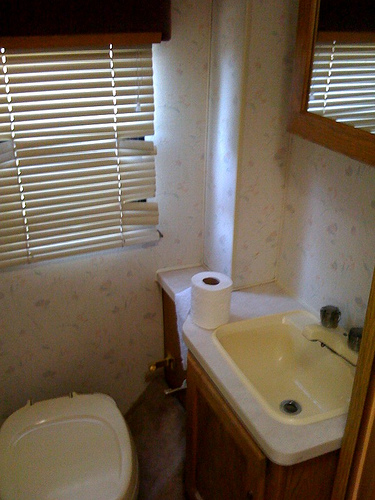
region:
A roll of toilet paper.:
[191, 270, 231, 330]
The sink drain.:
[278, 397, 300, 414]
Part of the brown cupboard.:
[186, 406, 224, 499]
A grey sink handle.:
[321, 305, 340, 327]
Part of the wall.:
[315, 207, 355, 237]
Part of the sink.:
[256, 346, 289, 376]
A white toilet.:
[1, 391, 140, 499]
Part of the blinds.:
[35, 74, 105, 184]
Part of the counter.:
[249, 293, 288, 305]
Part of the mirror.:
[321, 8, 357, 61]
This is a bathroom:
[143, 220, 265, 464]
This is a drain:
[278, 397, 299, 417]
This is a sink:
[221, 318, 328, 481]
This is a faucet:
[309, 295, 371, 375]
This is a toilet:
[24, 386, 117, 487]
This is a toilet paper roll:
[183, 277, 228, 311]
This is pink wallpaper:
[45, 278, 110, 377]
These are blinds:
[55, 203, 112, 240]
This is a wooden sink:
[168, 400, 258, 476]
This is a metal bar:
[155, 363, 202, 430]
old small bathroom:
[0, 0, 374, 499]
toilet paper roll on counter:
[174, 270, 234, 370]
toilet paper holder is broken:
[147, 352, 187, 395]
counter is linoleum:
[157, 264, 358, 466]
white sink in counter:
[211, 308, 355, 424]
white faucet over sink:
[302, 303, 361, 365]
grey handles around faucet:
[319, 304, 362, 352]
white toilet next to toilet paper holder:
[0, 391, 139, 499]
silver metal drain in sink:
[279, 399, 302, 414]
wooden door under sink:
[182, 354, 263, 499]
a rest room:
[10, 152, 341, 490]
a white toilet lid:
[0, 393, 140, 496]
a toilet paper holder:
[149, 353, 186, 398]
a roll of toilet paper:
[189, 270, 232, 330]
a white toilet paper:
[189, 271, 232, 332]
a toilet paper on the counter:
[181, 270, 349, 465]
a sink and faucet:
[214, 306, 357, 424]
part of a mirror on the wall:
[283, 36, 373, 164]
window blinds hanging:
[4, 34, 161, 267]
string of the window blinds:
[133, 46, 143, 111]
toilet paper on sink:
[178, 263, 243, 331]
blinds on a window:
[0, 60, 162, 269]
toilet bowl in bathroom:
[8, 387, 151, 497]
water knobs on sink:
[320, 299, 373, 350]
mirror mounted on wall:
[290, 1, 373, 166]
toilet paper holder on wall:
[142, 354, 190, 400]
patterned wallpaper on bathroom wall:
[234, 162, 322, 273]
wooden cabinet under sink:
[174, 383, 275, 498]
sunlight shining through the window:
[153, 70, 167, 148]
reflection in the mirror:
[327, 52, 368, 116]